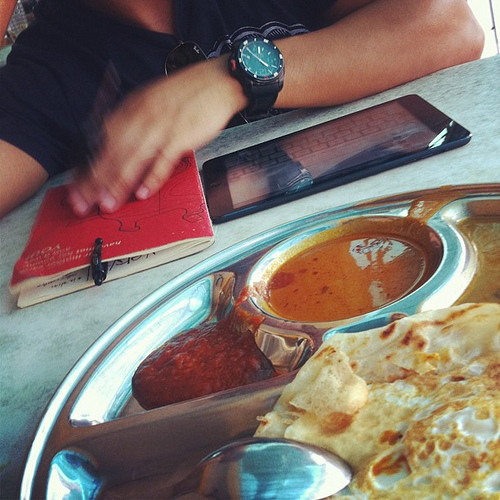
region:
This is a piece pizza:
[281, 347, 384, 421]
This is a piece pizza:
[347, 302, 438, 416]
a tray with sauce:
[259, 208, 423, 313]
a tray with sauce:
[147, 297, 273, 397]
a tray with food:
[307, 340, 499, 455]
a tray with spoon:
[168, 388, 344, 498]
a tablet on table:
[214, 90, 497, 201]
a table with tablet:
[241, 87, 493, 192]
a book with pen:
[30, 167, 175, 269]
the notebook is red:
[23, 177, 235, 294]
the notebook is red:
[42, 150, 202, 282]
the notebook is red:
[3, 134, 201, 280]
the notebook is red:
[16, 162, 216, 320]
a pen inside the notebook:
[76, 225, 123, 297]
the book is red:
[9, 152, 214, 309]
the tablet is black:
[203, 93, 472, 223]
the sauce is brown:
[270, 232, 426, 320]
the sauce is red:
[130, 282, 277, 409]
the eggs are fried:
[253, 303, 498, 498]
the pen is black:
[88, 236, 108, 286]